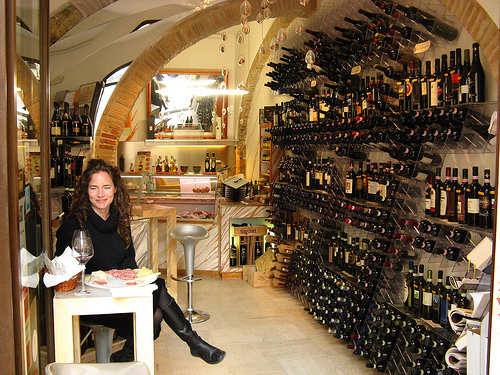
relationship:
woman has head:
[56, 160, 226, 365] [83, 163, 117, 211]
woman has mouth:
[56, 160, 226, 365] [95, 198, 110, 203]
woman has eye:
[56, 160, 226, 365] [88, 186, 99, 191]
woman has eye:
[56, 160, 226, 365] [104, 186, 111, 190]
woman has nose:
[56, 160, 226, 365] [97, 186, 105, 199]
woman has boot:
[56, 160, 226, 365] [161, 297, 226, 364]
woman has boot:
[56, 160, 226, 365] [110, 335, 134, 361]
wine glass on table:
[71, 229, 97, 298] [53, 274, 156, 375]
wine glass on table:
[71, 229, 89, 283] [53, 274, 156, 375]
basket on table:
[41, 266, 80, 292] [53, 274, 156, 375]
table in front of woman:
[53, 274, 156, 375] [56, 160, 226, 365]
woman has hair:
[56, 160, 226, 365] [63, 159, 132, 251]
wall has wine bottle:
[234, 0, 498, 375] [413, 16, 459, 42]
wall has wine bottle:
[234, 0, 498, 375] [467, 43, 484, 102]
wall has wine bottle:
[234, 0, 498, 375] [345, 161, 357, 200]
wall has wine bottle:
[234, 0, 498, 375] [402, 260, 413, 312]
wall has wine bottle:
[234, 0, 498, 375] [421, 271, 436, 321]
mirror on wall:
[145, 69, 229, 140] [50, 34, 235, 212]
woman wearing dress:
[56, 160, 226, 365] [54, 207, 165, 336]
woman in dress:
[56, 160, 226, 365] [54, 207, 165, 336]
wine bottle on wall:
[413, 16, 459, 42] [234, 0, 498, 375]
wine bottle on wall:
[467, 43, 484, 102] [234, 0, 498, 375]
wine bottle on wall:
[345, 161, 357, 200] [234, 0, 498, 375]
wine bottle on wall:
[402, 260, 413, 312] [234, 0, 498, 375]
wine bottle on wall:
[421, 271, 436, 321] [234, 0, 498, 375]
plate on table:
[83, 269, 158, 290] [53, 274, 156, 375]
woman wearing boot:
[56, 160, 226, 365] [161, 297, 226, 364]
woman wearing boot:
[56, 160, 226, 365] [110, 335, 134, 361]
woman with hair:
[56, 160, 226, 365] [63, 159, 132, 251]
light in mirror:
[154, 87, 249, 98] [145, 69, 229, 140]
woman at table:
[56, 160, 226, 365] [53, 274, 156, 375]